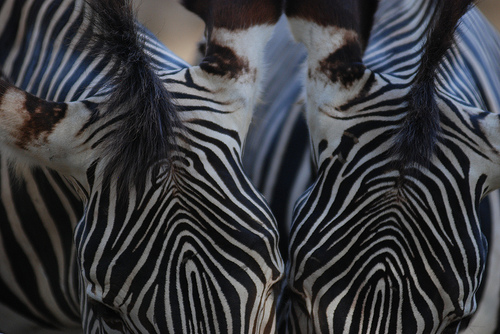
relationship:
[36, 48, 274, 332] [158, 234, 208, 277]
zebra has stripes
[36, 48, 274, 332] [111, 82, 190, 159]
zebra has hair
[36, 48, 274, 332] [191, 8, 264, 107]
zebra has ears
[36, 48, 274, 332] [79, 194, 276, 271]
zebra has head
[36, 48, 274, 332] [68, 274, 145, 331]
zebra has eyes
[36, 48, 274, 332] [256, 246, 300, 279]
zebra has face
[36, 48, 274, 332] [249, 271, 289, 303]
zebra has eye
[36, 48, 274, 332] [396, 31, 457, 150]
zebra has mane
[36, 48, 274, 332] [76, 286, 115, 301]
zebra has eyelid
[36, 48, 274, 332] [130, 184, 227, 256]
zebra has forehead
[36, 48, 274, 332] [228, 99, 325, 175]
zebra has stomach